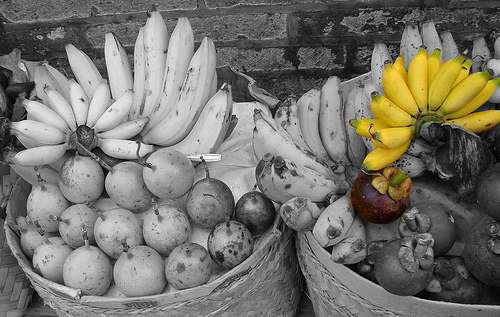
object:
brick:
[0, 0, 96, 25]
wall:
[4, 1, 499, 171]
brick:
[243, 50, 345, 68]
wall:
[5, 2, 496, 27]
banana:
[423, 51, 464, 116]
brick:
[346, 42, 393, 64]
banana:
[347, 110, 423, 177]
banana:
[315, 45, 487, 185]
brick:
[125, 3, 202, 17]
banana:
[438, 61, 493, 113]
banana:
[348, 112, 388, 139]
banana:
[441, 108, 498, 130]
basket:
[5, 178, 303, 315]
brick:
[85, 9, 290, 50]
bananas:
[353, 118, 428, 148]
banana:
[405, 43, 430, 117]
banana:
[379, 55, 419, 117]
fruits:
[141, 202, 190, 251]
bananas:
[364, 147, 404, 169]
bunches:
[197, 79, 236, 168]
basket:
[275, 42, 483, 314]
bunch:
[347, 29, 484, 205]